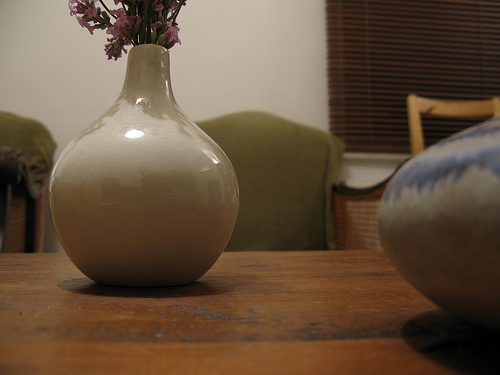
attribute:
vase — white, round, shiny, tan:
[48, 36, 240, 292]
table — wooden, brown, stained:
[6, 240, 494, 366]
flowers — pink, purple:
[69, 3, 185, 61]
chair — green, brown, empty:
[186, 109, 339, 246]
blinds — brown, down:
[328, 5, 499, 158]